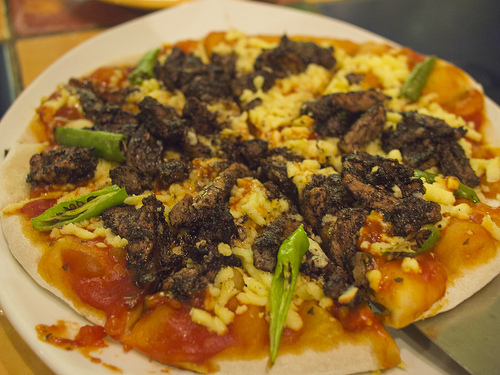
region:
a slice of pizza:
[263, 140, 491, 325]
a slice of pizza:
[130, 166, 402, 373]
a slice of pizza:
[9, 148, 236, 333]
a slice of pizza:
[213, 32, 340, 116]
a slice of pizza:
[268, 35, 473, 141]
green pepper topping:
[256, 219, 312, 362]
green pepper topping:
[26, 180, 126, 226]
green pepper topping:
[48, 120, 133, 170]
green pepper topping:
[398, 49, 441, 110]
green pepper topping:
[131, 40, 163, 85]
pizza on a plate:
[90, 45, 448, 336]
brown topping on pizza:
[141, 181, 234, 296]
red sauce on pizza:
[160, 296, 292, 351]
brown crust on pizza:
[220, 319, 384, 374]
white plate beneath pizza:
[12, 74, 54, 146]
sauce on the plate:
[32, 320, 119, 374]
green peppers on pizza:
[256, 228, 315, 343]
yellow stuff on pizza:
[223, 176, 280, 306]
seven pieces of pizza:
[59, 49, 452, 353]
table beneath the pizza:
[5, 12, 62, 71]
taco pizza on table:
[15, 2, 495, 354]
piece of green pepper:
[265, 227, 313, 362]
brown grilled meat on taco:
[114, 208, 231, 285]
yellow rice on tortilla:
[189, 276, 232, 343]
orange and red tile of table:
[7, 7, 92, 74]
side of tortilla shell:
[190, 345, 411, 373]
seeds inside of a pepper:
[59, 197, 98, 209]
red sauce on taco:
[54, 244, 144, 318]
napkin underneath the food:
[73, 0, 398, 31]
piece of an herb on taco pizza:
[392, 273, 409, 287]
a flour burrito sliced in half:
[0, 3, 490, 373]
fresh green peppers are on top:
[43, 45, 469, 358]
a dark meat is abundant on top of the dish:
[28, 46, 488, 328]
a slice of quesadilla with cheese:
[116, 158, 397, 373]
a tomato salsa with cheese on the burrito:
[82, 222, 258, 372]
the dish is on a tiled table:
[5, 1, 477, 372]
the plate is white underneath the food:
[8, 5, 494, 370]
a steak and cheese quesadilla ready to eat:
[20, 31, 497, 347]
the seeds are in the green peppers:
[36, 177, 313, 352]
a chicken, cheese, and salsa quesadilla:
[8, 30, 495, 367]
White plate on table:
[2, 253, 89, 373]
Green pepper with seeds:
[25, 176, 137, 240]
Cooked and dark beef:
[16, 133, 101, 196]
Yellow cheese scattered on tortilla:
[178, 272, 263, 345]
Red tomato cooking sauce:
[36, 245, 148, 330]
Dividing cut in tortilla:
[275, 156, 421, 371]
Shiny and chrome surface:
[396, 278, 496, 371]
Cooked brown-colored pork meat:
[151, 155, 248, 241]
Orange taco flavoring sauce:
[30, 226, 141, 327]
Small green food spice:
[446, 223, 476, 273]